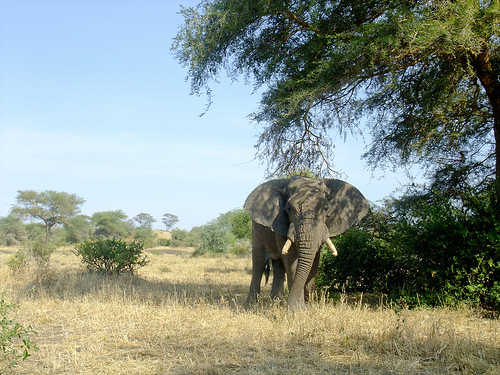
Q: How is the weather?
A: It is clear.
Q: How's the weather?
A: It is clear.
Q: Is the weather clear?
A: Yes, it is clear.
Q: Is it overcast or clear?
A: It is clear.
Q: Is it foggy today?
A: No, it is clear.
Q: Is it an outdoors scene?
A: Yes, it is outdoors.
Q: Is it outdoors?
A: Yes, it is outdoors.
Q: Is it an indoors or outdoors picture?
A: It is outdoors.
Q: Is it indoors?
A: No, it is outdoors.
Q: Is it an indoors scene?
A: No, it is outdoors.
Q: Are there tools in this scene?
A: No, there are no tools.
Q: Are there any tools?
A: No, there are no tools.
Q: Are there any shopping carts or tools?
A: No, there are no tools or shopping carts.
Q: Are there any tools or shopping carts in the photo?
A: No, there are no tools or shopping carts.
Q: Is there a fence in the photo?
A: No, there are no fences.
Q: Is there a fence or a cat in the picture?
A: No, there are no fences or cats.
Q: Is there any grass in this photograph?
A: Yes, there is grass.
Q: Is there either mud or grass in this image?
A: Yes, there is grass.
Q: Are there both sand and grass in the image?
A: No, there is grass but no sand.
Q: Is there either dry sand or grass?
A: Yes, there is dry grass.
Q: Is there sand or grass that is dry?
A: Yes, the grass is dry.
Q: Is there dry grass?
A: Yes, there is dry grass.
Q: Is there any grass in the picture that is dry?
A: Yes, there is grass that is dry.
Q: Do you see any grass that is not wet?
A: Yes, there is dry grass.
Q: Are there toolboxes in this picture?
A: No, there are no toolboxes.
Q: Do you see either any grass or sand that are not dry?
A: No, there is grass but it is dry.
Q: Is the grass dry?
A: Yes, the grass is dry.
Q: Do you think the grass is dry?
A: Yes, the grass is dry.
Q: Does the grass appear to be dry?
A: Yes, the grass is dry.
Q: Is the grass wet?
A: No, the grass is dry.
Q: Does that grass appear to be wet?
A: No, the grass is dry.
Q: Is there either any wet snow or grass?
A: No, there is grass but it is dry.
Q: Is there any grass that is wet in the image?
A: No, there is grass but it is dry.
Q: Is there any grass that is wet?
A: No, there is grass but it is dry.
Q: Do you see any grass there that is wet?
A: No, there is grass but it is dry.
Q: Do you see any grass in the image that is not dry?
A: No, there is grass but it is dry.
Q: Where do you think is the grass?
A: The grass is on the ground.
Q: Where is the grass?
A: The grass is on the ground.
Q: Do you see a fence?
A: No, there are no fences.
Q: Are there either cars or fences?
A: No, there are no fences or cars.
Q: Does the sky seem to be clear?
A: Yes, the sky is clear.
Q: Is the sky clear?
A: Yes, the sky is clear.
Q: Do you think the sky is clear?
A: Yes, the sky is clear.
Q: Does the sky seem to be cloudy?
A: No, the sky is clear.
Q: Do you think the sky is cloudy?
A: No, the sky is clear.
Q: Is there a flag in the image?
A: No, there are no flags.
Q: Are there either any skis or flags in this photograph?
A: No, there are no flags or skis.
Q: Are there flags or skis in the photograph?
A: No, there are no flags or skis.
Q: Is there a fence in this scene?
A: No, there are no fences.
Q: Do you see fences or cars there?
A: No, there are no fences or cars.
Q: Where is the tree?
A: The tree is on the hill.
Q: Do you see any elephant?
A: Yes, there is an elephant.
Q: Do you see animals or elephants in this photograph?
A: Yes, there is an elephant.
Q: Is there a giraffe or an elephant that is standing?
A: Yes, the elephant is standing.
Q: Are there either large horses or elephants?
A: Yes, there is a large elephant.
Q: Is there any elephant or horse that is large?
A: Yes, the elephant is large.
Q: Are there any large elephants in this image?
A: Yes, there is a large elephant.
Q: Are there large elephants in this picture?
A: Yes, there is a large elephant.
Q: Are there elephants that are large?
A: Yes, there is an elephant that is large.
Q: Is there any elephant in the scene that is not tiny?
A: Yes, there is a large elephant.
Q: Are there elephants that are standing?
A: Yes, there is an elephant that is standing.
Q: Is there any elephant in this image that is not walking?
A: Yes, there is an elephant that is standing.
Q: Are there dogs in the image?
A: No, there are no dogs.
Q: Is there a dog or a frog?
A: No, there are no dogs or frogs.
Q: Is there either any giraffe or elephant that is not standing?
A: No, there is an elephant but it is standing.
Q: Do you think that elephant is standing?
A: Yes, the elephant is standing.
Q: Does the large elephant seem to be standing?
A: Yes, the elephant is standing.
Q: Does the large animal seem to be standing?
A: Yes, the elephant is standing.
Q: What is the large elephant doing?
A: The elephant is standing.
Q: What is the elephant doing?
A: The elephant is standing.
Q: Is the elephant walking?
A: No, the elephant is standing.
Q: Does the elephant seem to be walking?
A: No, the elephant is standing.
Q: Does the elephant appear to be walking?
A: No, the elephant is standing.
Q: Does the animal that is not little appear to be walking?
A: No, the elephant is standing.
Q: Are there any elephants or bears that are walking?
A: No, there is an elephant but it is standing.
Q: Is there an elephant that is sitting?
A: No, there is an elephant but it is standing.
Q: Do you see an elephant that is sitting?
A: No, there is an elephant but it is standing.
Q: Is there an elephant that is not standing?
A: No, there is an elephant but it is standing.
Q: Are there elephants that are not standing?
A: No, there is an elephant but it is standing.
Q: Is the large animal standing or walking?
A: The elephant is standing.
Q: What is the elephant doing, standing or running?
A: The elephant is standing.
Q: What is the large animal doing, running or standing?
A: The elephant is standing.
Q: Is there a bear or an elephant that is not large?
A: No, there is an elephant but it is large.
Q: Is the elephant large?
A: Yes, the elephant is large.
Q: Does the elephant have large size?
A: Yes, the elephant is large.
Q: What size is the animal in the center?
A: The elephant is large.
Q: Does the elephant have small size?
A: No, the elephant is large.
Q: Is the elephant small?
A: No, the elephant is large.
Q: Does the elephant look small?
A: No, the elephant is large.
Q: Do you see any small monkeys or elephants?
A: No, there is an elephant but it is large.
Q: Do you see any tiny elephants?
A: No, there is an elephant but it is large.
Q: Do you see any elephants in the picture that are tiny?
A: No, there is an elephant but it is large.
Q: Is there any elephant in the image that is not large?
A: No, there is an elephant but it is large.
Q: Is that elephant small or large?
A: The elephant is large.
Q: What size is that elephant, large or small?
A: The elephant is large.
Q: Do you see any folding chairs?
A: No, there are no folding chairs.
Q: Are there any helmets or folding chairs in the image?
A: No, there are no folding chairs or helmets.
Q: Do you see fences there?
A: No, there are no fences.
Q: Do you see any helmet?
A: No, there are no helmets.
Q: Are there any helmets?
A: No, there are no helmets.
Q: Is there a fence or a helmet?
A: No, there are no helmets or fences.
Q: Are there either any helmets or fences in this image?
A: No, there are no helmets or fences.